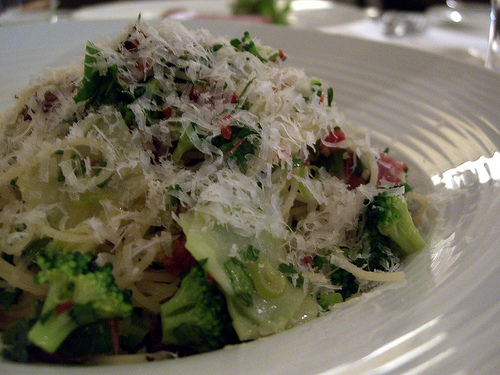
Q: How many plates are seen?
A: 1.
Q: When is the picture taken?
A: Daytime.